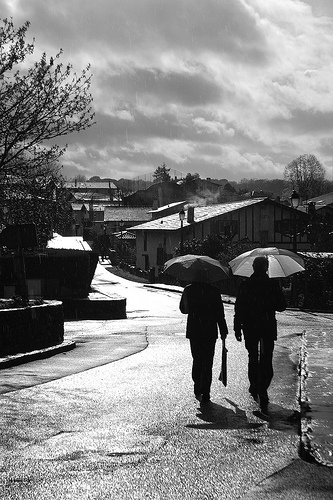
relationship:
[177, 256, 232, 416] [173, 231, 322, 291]
people carrying umbrellas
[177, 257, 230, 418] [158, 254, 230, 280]
person holding umbrella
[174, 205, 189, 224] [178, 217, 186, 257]
street light on pole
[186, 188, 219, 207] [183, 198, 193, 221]
smoke exit from chimney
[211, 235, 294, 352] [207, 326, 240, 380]
person carrying bag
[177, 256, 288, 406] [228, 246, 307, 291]
people holding umbrella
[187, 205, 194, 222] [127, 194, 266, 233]
chimney on a roof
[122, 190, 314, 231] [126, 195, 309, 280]
roof of building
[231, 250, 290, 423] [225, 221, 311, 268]
person holding umbrella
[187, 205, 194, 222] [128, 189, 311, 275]
chimney on top of building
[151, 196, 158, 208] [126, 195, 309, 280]
chimney on top of building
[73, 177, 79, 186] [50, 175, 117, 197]
chimney on top of building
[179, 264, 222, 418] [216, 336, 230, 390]
person holding bag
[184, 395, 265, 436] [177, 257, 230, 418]
shadow of person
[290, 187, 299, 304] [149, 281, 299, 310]
street lamp on sidewalk